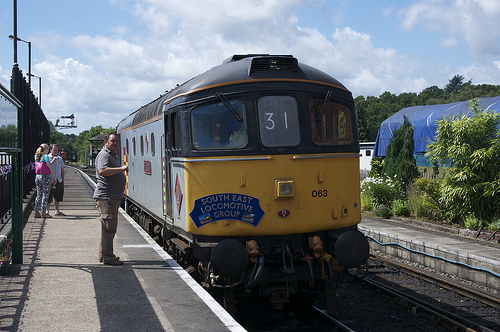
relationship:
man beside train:
[94, 130, 136, 264] [113, 51, 368, 292]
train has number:
[113, 51, 368, 292] [257, 103, 295, 135]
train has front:
[113, 51, 368, 292] [184, 93, 362, 238]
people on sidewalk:
[30, 142, 72, 218] [5, 162, 236, 326]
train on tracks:
[113, 51, 368, 292] [247, 253, 492, 327]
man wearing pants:
[94, 130, 136, 264] [95, 199, 124, 262]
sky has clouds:
[5, 3, 498, 141] [40, 5, 463, 122]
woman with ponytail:
[34, 142, 54, 221] [34, 147, 47, 165]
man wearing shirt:
[94, 130, 136, 264] [91, 147, 130, 200]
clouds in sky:
[40, 5, 463, 122] [5, 3, 498, 141]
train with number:
[113, 51, 368, 292] [257, 103, 295, 135]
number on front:
[257, 103, 295, 135] [184, 93, 362, 238]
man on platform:
[94, 130, 136, 264] [7, 160, 237, 331]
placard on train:
[190, 193, 267, 226] [113, 51, 368, 292]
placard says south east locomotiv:
[190, 193, 267, 226] [202, 190, 255, 219]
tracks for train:
[247, 253, 492, 327] [113, 51, 368, 292]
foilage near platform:
[363, 95, 499, 225] [363, 205, 500, 277]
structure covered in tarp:
[367, 96, 500, 174] [372, 96, 499, 161]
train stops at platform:
[113, 51, 368, 292] [7, 160, 237, 331]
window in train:
[258, 96, 300, 147] [113, 51, 368, 292]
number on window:
[257, 103, 295, 135] [258, 96, 300, 147]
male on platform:
[94, 130, 136, 264] [7, 160, 237, 331]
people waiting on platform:
[30, 142, 72, 218] [7, 160, 237, 331]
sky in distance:
[5, 3, 498, 141] [7, 0, 499, 154]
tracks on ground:
[247, 253, 492, 327] [243, 249, 500, 327]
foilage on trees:
[0, 75, 499, 162] [1, 75, 499, 231]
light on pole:
[9, 35, 20, 43] [26, 42, 35, 92]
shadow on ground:
[15, 253, 162, 331] [5, 162, 236, 326]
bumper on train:
[210, 227, 372, 283] [113, 51, 368, 292]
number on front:
[312, 185, 330, 199] [184, 93, 362, 238]